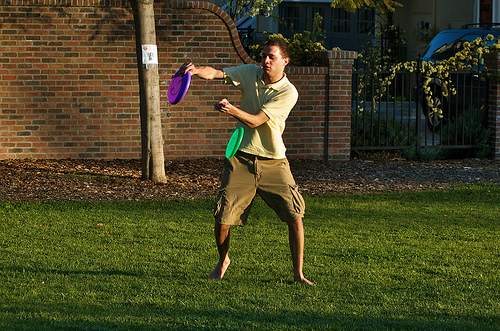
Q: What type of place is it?
A: It is a park.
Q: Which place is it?
A: It is a park.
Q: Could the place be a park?
A: Yes, it is a park.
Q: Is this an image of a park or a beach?
A: It is showing a park.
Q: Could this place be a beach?
A: No, it is a park.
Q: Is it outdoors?
A: Yes, it is outdoors.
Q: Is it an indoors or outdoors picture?
A: It is outdoors.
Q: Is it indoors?
A: No, it is outdoors.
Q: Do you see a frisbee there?
A: Yes, there is a frisbee.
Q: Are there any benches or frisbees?
A: Yes, there is a frisbee.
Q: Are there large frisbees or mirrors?
A: Yes, there is a large frisbee.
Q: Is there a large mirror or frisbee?
A: Yes, there is a large frisbee.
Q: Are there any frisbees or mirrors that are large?
A: Yes, the frisbee is large.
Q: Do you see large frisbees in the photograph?
A: Yes, there is a large frisbee.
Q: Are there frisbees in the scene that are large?
A: Yes, there is a frisbee that is large.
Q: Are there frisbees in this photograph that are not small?
A: Yes, there is a large frisbee.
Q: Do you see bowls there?
A: No, there are no bowls.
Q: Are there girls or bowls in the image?
A: No, there are no bowls or girls.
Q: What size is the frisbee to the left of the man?
A: The frisbee is large.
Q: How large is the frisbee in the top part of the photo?
A: The frisbee is large.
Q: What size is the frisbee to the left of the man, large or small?
A: The frisbee is large.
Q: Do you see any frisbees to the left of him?
A: Yes, there is a frisbee to the left of the man.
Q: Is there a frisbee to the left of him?
A: Yes, there is a frisbee to the left of the man.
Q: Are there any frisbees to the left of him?
A: Yes, there is a frisbee to the left of the man.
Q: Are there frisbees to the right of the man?
A: No, the frisbee is to the left of the man.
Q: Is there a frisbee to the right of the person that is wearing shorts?
A: No, the frisbee is to the left of the man.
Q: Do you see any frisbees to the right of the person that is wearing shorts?
A: No, the frisbee is to the left of the man.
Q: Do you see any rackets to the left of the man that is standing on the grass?
A: No, there is a frisbee to the left of the man.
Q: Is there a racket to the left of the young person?
A: No, there is a frisbee to the left of the man.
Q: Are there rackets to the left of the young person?
A: No, there is a frisbee to the left of the man.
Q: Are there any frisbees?
A: Yes, there is a frisbee.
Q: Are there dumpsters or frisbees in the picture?
A: Yes, there is a frisbee.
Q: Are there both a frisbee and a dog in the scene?
A: No, there is a frisbee but no dogs.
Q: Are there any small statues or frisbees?
A: Yes, there is a small frisbee.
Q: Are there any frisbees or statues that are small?
A: Yes, the frisbee is small.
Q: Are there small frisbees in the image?
A: Yes, there is a small frisbee.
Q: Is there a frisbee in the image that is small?
A: Yes, there is a frisbee that is small.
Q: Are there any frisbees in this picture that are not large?
A: Yes, there is a small frisbee.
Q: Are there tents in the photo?
A: No, there are no tents.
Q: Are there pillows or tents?
A: No, there are no tents or pillows.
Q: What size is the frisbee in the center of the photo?
A: The frisbee is small.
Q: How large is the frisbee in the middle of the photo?
A: The frisbee is small.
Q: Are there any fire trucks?
A: No, there are no fire trucks.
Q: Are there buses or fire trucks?
A: No, there are no fire trucks or buses.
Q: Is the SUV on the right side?
A: Yes, the SUV is on the right of the image.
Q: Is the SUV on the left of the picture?
A: No, the SUV is on the right of the image.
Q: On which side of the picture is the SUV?
A: The SUV is on the right of the image.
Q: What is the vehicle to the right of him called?
A: The vehicle is a SUV.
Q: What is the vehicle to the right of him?
A: The vehicle is a SUV.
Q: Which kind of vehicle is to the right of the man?
A: The vehicle is a SUV.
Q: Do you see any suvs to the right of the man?
A: Yes, there is a SUV to the right of the man.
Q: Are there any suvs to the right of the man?
A: Yes, there is a SUV to the right of the man.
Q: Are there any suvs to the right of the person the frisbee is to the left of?
A: Yes, there is a SUV to the right of the man.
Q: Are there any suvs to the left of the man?
A: No, the SUV is to the right of the man.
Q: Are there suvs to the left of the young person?
A: No, the SUV is to the right of the man.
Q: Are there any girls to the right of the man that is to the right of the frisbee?
A: No, there is a SUV to the right of the man.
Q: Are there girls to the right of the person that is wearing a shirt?
A: No, there is a SUV to the right of the man.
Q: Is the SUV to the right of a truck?
A: No, the SUV is to the right of the man.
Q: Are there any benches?
A: No, there are no benches.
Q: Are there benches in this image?
A: No, there are no benches.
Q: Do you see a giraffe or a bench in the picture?
A: No, there are no benches or giraffes.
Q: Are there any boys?
A: No, there are no boys.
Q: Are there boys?
A: No, there are no boys.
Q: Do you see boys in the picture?
A: No, there are no boys.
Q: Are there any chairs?
A: No, there are no chairs.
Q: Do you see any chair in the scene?
A: No, there are no chairs.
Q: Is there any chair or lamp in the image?
A: No, there are no chairs or lamps.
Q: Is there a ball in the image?
A: No, there are no balls.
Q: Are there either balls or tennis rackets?
A: No, there are no balls or tennis rackets.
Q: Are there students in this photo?
A: No, there are no students.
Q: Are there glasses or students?
A: No, there are no students or glasses.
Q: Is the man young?
A: Yes, the man is young.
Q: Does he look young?
A: Yes, the man is young.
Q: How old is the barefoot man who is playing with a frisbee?
A: The man is young.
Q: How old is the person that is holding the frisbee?
A: The man is young.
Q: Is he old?
A: No, the man is young.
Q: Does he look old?
A: No, the man is young.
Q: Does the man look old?
A: No, the man is young.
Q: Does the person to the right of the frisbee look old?
A: No, the man is young.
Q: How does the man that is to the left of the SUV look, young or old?
A: The man is young.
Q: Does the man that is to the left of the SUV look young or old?
A: The man is young.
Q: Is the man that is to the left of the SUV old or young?
A: The man is young.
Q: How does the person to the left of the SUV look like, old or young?
A: The man is young.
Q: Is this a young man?
A: Yes, this is a young man.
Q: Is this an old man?
A: No, this is a young man.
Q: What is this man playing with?
A: The man is playing with a frisbee.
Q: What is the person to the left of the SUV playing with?
A: The man is playing with a frisbee.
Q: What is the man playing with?
A: The man is playing with a frisbee.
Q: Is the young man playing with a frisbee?
A: Yes, the man is playing with a frisbee.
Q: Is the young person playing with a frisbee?
A: Yes, the man is playing with a frisbee.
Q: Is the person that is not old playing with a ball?
A: No, the man is playing with a frisbee.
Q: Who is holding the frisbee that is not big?
A: The man is holding the frisbee.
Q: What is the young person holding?
A: The man is holding the frisbee.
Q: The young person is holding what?
A: The man is holding the frisbee.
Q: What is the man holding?
A: The man is holding the frisbee.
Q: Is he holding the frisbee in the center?
A: Yes, the man is holding the frisbee.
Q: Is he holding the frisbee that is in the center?
A: Yes, the man is holding the frisbee.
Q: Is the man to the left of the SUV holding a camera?
A: No, the man is holding the frisbee.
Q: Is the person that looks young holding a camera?
A: No, the man is holding the frisbee.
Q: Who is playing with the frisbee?
A: The man is playing with the frisbee.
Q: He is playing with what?
A: The man is playing with a frisbee.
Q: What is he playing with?
A: The man is playing with a frisbee.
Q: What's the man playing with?
A: The man is playing with a frisbee.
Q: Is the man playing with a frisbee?
A: Yes, the man is playing with a frisbee.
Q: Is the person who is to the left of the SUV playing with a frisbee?
A: Yes, the man is playing with a frisbee.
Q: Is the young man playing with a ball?
A: No, the man is playing with a frisbee.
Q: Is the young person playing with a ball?
A: No, the man is playing with a frisbee.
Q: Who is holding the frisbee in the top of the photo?
A: The man is holding the frisbee.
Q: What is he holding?
A: The man is holding the frisbee.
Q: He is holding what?
A: The man is holding the frisbee.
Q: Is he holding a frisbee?
A: Yes, the man is holding a frisbee.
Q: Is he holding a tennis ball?
A: No, the man is holding a frisbee.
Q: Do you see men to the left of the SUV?
A: Yes, there is a man to the left of the SUV.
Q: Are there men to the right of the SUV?
A: No, the man is to the left of the SUV.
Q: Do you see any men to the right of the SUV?
A: No, the man is to the left of the SUV.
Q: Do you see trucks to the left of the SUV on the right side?
A: No, there is a man to the left of the SUV.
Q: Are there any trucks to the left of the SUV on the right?
A: No, there is a man to the left of the SUV.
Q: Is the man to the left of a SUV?
A: Yes, the man is to the left of a SUV.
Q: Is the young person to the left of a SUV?
A: Yes, the man is to the left of a SUV.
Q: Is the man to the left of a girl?
A: No, the man is to the left of a SUV.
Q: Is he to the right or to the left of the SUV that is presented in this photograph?
A: The man is to the left of the SUV.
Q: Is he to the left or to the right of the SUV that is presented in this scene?
A: The man is to the left of the SUV.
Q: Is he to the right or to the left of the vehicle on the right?
A: The man is to the left of the SUV.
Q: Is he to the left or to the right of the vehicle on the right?
A: The man is to the left of the SUV.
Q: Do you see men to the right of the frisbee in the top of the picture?
A: Yes, there is a man to the right of the frisbee.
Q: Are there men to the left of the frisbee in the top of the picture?
A: No, the man is to the right of the frisbee.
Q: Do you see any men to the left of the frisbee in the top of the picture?
A: No, the man is to the right of the frisbee.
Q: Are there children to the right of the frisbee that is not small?
A: No, there is a man to the right of the frisbee.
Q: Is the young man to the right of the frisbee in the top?
A: Yes, the man is to the right of the frisbee.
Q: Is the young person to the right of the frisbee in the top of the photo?
A: Yes, the man is to the right of the frisbee.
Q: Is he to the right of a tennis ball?
A: No, the man is to the right of the frisbee.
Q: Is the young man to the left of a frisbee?
A: No, the man is to the right of a frisbee.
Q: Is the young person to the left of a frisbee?
A: No, the man is to the right of a frisbee.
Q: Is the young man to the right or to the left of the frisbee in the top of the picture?
A: The man is to the right of the frisbee.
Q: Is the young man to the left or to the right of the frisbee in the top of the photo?
A: The man is to the right of the frisbee.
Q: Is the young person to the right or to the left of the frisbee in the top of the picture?
A: The man is to the right of the frisbee.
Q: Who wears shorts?
A: The man wears shorts.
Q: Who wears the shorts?
A: The man wears shorts.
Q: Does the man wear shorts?
A: Yes, the man wears shorts.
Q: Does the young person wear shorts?
A: Yes, the man wears shorts.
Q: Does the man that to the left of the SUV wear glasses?
A: No, the man wears shorts.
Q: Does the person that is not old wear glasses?
A: No, the man wears shorts.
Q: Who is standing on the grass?
A: The man is standing on the grass.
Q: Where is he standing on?
A: The man is standing on the grass.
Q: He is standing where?
A: The man is standing on the grass.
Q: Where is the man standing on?
A: The man is standing on the grass.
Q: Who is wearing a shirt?
A: The man is wearing a shirt.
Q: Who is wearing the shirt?
A: The man is wearing a shirt.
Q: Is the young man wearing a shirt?
A: Yes, the man is wearing a shirt.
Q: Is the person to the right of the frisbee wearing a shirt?
A: Yes, the man is wearing a shirt.